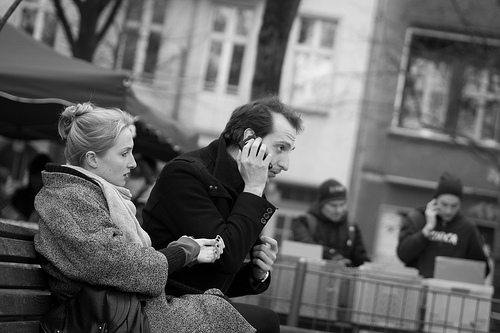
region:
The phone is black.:
[239, 134, 283, 175]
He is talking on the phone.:
[217, 106, 303, 181]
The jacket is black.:
[139, 146, 281, 301]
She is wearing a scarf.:
[65, 160, 168, 255]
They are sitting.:
[42, 77, 279, 331]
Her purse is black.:
[33, 288, 149, 328]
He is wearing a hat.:
[423, 165, 481, 230]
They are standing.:
[254, 158, 493, 304]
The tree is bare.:
[378, 10, 497, 157]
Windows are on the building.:
[18, 4, 497, 159]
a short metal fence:
[268, 255, 498, 331]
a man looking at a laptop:
[399, 169, 494, 291]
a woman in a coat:
[28, 97, 258, 332]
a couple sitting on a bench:
[0, 94, 309, 331]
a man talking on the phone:
[141, 98, 288, 332]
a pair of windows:
[396, 42, 496, 154]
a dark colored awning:
[2, 13, 213, 161]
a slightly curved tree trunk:
[254, 8, 296, 98]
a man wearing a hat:
[292, 179, 373, 259]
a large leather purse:
[33, 273, 152, 331]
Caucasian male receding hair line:
[267, 100, 303, 142]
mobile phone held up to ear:
[237, 127, 273, 187]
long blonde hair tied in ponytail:
[53, 98, 131, 164]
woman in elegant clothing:
[26, 94, 257, 331]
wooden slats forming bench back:
[1, 220, 34, 330]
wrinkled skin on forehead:
[279, 128, 300, 142]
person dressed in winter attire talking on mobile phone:
[395, 169, 497, 275]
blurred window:
[278, 11, 331, 117]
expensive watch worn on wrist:
[259, 265, 270, 286]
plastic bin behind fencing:
[426, 277, 490, 330]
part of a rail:
[407, 296, 419, 308]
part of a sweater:
[79, 292, 94, 312]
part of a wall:
[325, 138, 337, 158]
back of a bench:
[28, 280, 38, 300]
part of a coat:
[184, 313, 191, 318]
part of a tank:
[356, 285, 362, 297]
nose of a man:
[286, 162, 288, 169]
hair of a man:
[246, 121, 253, 138]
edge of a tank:
[359, 268, 365, 276]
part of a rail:
[371, 302, 381, 310]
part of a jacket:
[196, 214, 204, 229]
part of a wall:
[363, 105, 367, 131]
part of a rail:
[353, 281, 367, 299]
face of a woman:
[117, 143, 124, 188]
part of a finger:
[201, 245, 212, 263]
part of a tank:
[316, 300, 322, 314]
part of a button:
[261, 218, 266, 230]